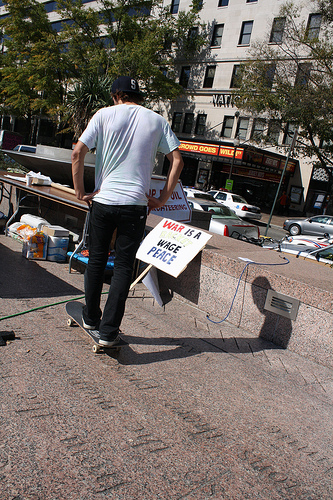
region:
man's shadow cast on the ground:
[157, 318, 295, 368]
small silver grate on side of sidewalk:
[264, 283, 321, 332]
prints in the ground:
[60, 384, 258, 478]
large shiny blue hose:
[211, 257, 255, 332]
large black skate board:
[52, 288, 120, 361]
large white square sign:
[132, 215, 212, 289]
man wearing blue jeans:
[60, 198, 173, 337]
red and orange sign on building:
[177, 135, 245, 165]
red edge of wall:
[230, 237, 308, 313]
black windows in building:
[197, 16, 281, 66]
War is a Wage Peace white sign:
[135, 216, 213, 276]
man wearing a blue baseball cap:
[63, 74, 184, 353]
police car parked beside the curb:
[207, 186, 262, 218]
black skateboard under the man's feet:
[63, 300, 129, 353]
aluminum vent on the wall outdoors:
[263, 288, 301, 321]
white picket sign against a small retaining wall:
[135, 217, 212, 285]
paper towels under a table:
[48, 236, 69, 262]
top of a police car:
[183, 184, 215, 200]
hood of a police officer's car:
[283, 232, 332, 245]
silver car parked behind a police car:
[281, 213, 331, 236]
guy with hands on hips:
[71, 70, 181, 230]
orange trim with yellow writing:
[185, 125, 252, 168]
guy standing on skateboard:
[51, 67, 189, 372]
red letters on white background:
[157, 214, 186, 236]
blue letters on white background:
[146, 246, 179, 273]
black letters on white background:
[155, 240, 183, 254]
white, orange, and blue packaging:
[7, 215, 54, 270]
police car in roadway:
[201, 183, 273, 229]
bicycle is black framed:
[233, 222, 316, 260]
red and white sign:
[148, 172, 195, 220]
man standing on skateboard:
[47, 69, 202, 352]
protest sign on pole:
[134, 220, 217, 279]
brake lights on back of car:
[220, 221, 263, 240]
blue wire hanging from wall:
[219, 257, 274, 303]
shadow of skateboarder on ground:
[126, 324, 250, 368]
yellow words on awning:
[188, 140, 252, 160]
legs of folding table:
[58, 204, 94, 282]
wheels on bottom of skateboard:
[61, 316, 105, 358]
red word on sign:
[163, 218, 186, 236]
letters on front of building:
[206, 89, 257, 111]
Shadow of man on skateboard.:
[89, 284, 312, 367]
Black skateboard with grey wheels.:
[46, 298, 124, 356]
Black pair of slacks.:
[86, 198, 142, 345]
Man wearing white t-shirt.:
[91, 74, 184, 202]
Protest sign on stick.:
[124, 216, 221, 284]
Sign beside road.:
[146, 170, 190, 218]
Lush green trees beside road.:
[14, 11, 62, 130]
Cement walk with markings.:
[37, 376, 296, 489]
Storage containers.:
[12, 216, 53, 264]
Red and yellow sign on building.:
[179, 139, 267, 162]